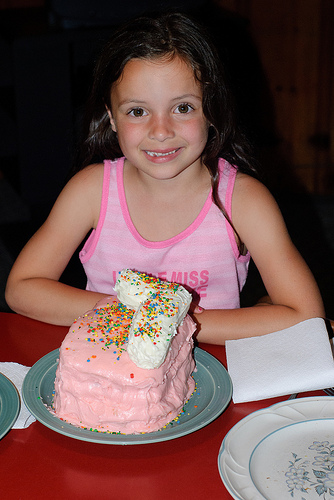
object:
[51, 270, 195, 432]
frost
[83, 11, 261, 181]
dark hair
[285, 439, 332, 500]
pattern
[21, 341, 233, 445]
plate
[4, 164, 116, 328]
arm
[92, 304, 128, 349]
sprinkles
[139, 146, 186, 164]
mouth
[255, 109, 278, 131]
ground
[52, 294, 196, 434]
pink frosting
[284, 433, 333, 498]
decoration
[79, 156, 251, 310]
shirt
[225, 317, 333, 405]
napkin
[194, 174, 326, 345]
girl's arm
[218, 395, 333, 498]
plate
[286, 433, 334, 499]
design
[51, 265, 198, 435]
birthday cake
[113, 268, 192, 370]
small cake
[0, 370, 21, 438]
plate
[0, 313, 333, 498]
table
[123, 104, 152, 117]
eye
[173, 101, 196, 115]
eye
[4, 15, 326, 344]
girl